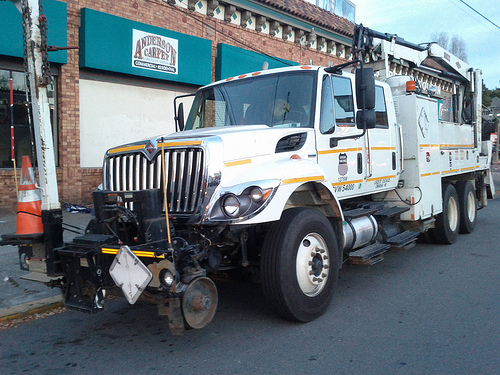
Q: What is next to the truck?
A: A pole.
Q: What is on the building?
A: Assorted signs.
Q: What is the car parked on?
A: The street.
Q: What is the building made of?
A: Bricks.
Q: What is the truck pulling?
A: Bucket lift.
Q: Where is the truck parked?
A: On the street.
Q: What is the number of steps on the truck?
A: Two.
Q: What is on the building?
A: A sign.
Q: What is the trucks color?
A: White.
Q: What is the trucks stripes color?
A: Yellow.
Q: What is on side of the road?
A: Warning cone.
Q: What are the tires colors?
A: White and black.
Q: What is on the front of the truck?
A: Metal grate.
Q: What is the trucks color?
A: White.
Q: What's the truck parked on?
A: Street.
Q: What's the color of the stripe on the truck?
A: Yellow.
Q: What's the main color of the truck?
A: White.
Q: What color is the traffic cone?
A: Orange and white.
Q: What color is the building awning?
A: Blue.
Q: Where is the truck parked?
A: On the street.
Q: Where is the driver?
A: In the truck.